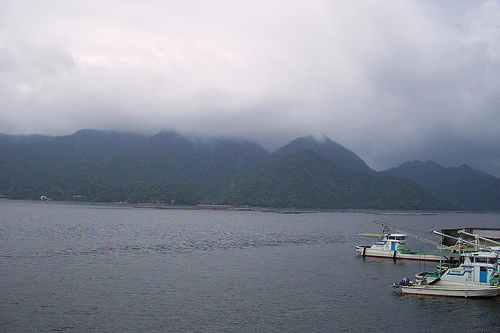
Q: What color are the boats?
A: White.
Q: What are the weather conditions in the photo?
A: Cloudy.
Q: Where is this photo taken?
A: By water.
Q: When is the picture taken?
A: In the daytime.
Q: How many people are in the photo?
A: Zero.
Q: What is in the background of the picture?
A: Mountains.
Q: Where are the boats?
A: On the water.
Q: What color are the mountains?
A: Green.